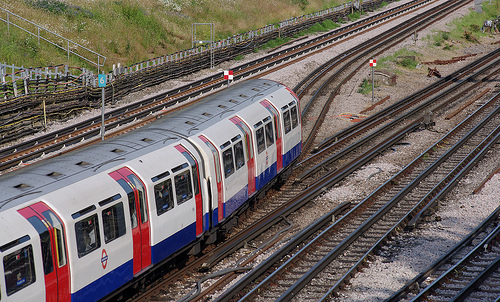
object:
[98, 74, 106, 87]
blue sign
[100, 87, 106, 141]
metal pole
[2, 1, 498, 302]
railyard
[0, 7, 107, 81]
fence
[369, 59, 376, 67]
sign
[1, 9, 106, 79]
rail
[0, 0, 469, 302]
gravel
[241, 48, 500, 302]
track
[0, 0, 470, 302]
track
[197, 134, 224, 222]
door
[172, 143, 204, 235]
door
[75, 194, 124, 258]
windows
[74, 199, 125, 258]
windows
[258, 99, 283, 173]
doors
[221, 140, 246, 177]
window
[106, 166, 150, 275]
door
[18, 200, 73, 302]
doors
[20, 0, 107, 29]
grass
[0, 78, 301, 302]
train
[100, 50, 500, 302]
gravel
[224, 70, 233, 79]
sign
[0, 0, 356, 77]
hill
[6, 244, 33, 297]
windows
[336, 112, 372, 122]
spraypaint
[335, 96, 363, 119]
ground